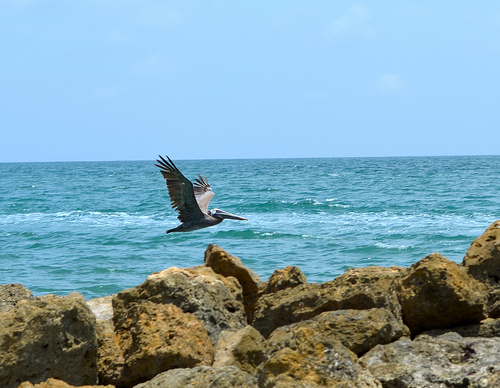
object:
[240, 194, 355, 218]
waves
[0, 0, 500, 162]
cloud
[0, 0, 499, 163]
blue sky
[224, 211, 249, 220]
beak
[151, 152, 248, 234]
bird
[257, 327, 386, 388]
rocks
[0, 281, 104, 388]
rocks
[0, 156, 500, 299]
ocean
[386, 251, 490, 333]
rock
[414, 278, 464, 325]
moss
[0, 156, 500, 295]
water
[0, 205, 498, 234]
wave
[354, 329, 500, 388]
rocks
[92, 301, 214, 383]
rocks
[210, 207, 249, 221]
head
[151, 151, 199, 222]
wing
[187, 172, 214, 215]
wing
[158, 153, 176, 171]
feathers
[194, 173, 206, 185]
feathers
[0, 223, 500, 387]
sea shore